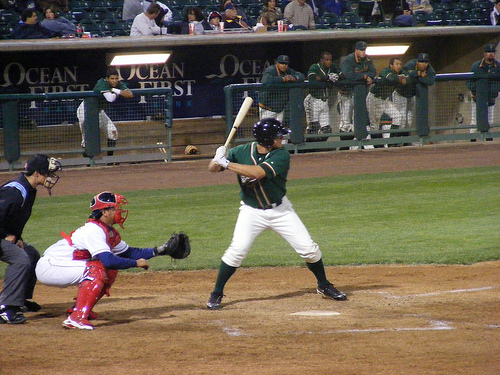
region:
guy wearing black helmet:
[197, 91, 360, 317]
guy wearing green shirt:
[206, 96, 352, 313]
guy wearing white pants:
[197, 88, 362, 317]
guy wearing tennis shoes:
[203, 97, 353, 311]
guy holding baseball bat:
[199, 89, 351, 311]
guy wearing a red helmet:
[38, 183, 198, 329]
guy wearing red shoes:
[35, 187, 195, 337]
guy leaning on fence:
[68, 70, 153, 170]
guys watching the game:
[255, 37, 498, 152]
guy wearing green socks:
[195, 95, 356, 314]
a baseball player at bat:
[203, 89, 345, 312]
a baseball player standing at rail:
[259, 56, 301, 149]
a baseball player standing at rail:
[305, 50, 336, 149]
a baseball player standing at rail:
[337, 40, 374, 145]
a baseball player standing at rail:
[368, 54, 406, 146]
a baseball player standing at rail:
[401, 51, 433, 141]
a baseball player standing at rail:
[470, 47, 498, 134]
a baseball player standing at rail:
[77, 73, 134, 155]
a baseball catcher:
[35, 189, 190, 329]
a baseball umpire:
[0, 153, 59, 318]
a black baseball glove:
[153, 222, 193, 267]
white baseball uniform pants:
[217, 201, 325, 273]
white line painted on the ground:
[228, 309, 283, 364]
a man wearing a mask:
[84, 184, 142, 244]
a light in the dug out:
[101, 46, 191, 80]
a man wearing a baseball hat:
[261, 47, 306, 105]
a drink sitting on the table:
[262, 12, 304, 45]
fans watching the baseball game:
[181, 5, 242, 32]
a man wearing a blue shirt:
[91, 217, 148, 284]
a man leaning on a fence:
[88, 60, 150, 145]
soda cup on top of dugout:
[262, 23, 287, 33]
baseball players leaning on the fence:
[281, 64, 421, 85]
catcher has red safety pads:
[83, 253, 103, 310]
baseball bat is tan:
[213, 93, 256, 140]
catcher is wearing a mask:
[107, 188, 143, 231]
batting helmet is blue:
[265, 113, 289, 139]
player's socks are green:
[217, 261, 236, 295]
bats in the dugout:
[153, 137, 179, 162]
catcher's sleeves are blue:
[105, 247, 123, 270]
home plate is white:
[278, 288, 336, 319]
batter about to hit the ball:
[203, 96, 349, 308]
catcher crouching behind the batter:
[31, 190, 193, 332]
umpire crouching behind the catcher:
[1, 152, 61, 328]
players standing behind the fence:
[74, 39, 499, 167]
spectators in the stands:
[1, 0, 498, 40]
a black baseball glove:
[164, 230, 193, 260]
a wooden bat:
[218, 93, 252, 147]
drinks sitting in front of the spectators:
[40, 16, 295, 38]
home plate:
[290, 306, 344, 321]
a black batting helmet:
[250, 117, 292, 147]